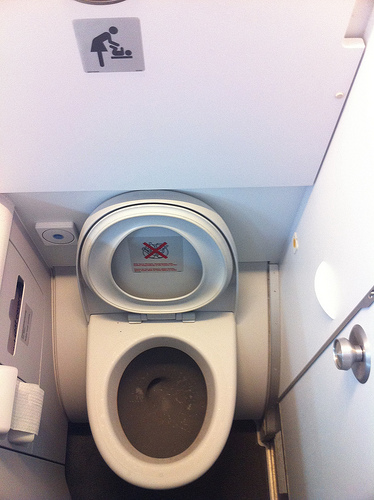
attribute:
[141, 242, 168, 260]
x — red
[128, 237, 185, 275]
sign — warning, white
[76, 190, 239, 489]
toilet — dirty, black, confined, ona airplane, airline toilet, white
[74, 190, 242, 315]
edge — white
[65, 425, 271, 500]
mat — black, speckled, gray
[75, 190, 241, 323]
lid — up, open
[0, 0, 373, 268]
wall — white, plastic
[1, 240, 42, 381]
tissue holder — white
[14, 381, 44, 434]
toilet paper — white, a roll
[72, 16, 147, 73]
symbol — diaper changing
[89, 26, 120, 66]
woman — black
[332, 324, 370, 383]
knob — circular, silver, metal, door handle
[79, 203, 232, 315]
toilet seat — white, raised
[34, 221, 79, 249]
sensor — square, white, blue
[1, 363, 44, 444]
rack — white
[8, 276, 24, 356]
slot — for covers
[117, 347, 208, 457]
bowl — gray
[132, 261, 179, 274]
lettering — red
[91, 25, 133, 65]
graphic — black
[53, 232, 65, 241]
button — blue